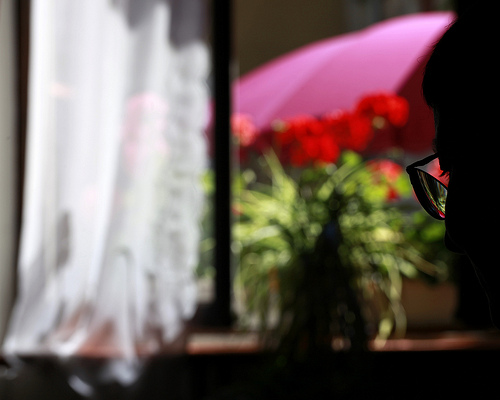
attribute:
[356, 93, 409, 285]
flower — long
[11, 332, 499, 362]
sill — brown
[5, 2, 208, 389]
curtain — white 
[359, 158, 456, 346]
stem — green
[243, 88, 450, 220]
flowers — red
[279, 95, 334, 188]
flower — red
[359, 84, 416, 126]
flower — purple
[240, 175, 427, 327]
stems — green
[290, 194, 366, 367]
object — large, black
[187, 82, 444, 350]
flowers — red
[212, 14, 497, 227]
umbrella — purple 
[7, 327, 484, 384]
window sill — wooden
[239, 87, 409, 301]
flowers — red